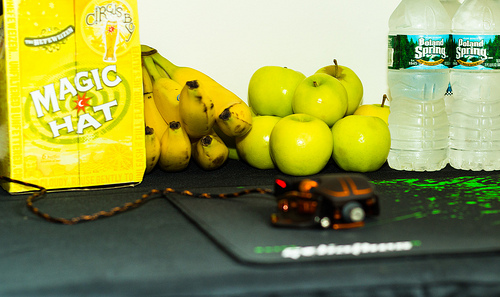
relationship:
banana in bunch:
[153, 71, 217, 141] [133, 39, 256, 176]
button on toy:
[343, 202, 367, 224] [268, 161, 377, 238]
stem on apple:
[331, 57, 343, 79] [311, 57, 367, 115]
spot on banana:
[193, 95, 208, 104] [153, 71, 217, 141]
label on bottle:
[384, 32, 454, 76] [381, 1, 453, 173]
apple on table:
[265, 114, 336, 178] [2, 161, 495, 297]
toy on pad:
[268, 161, 377, 238] [160, 165, 499, 266]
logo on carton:
[18, 59, 137, 146] [0, 0, 148, 198]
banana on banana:
[153, 71, 217, 141] [137, 84, 195, 172]